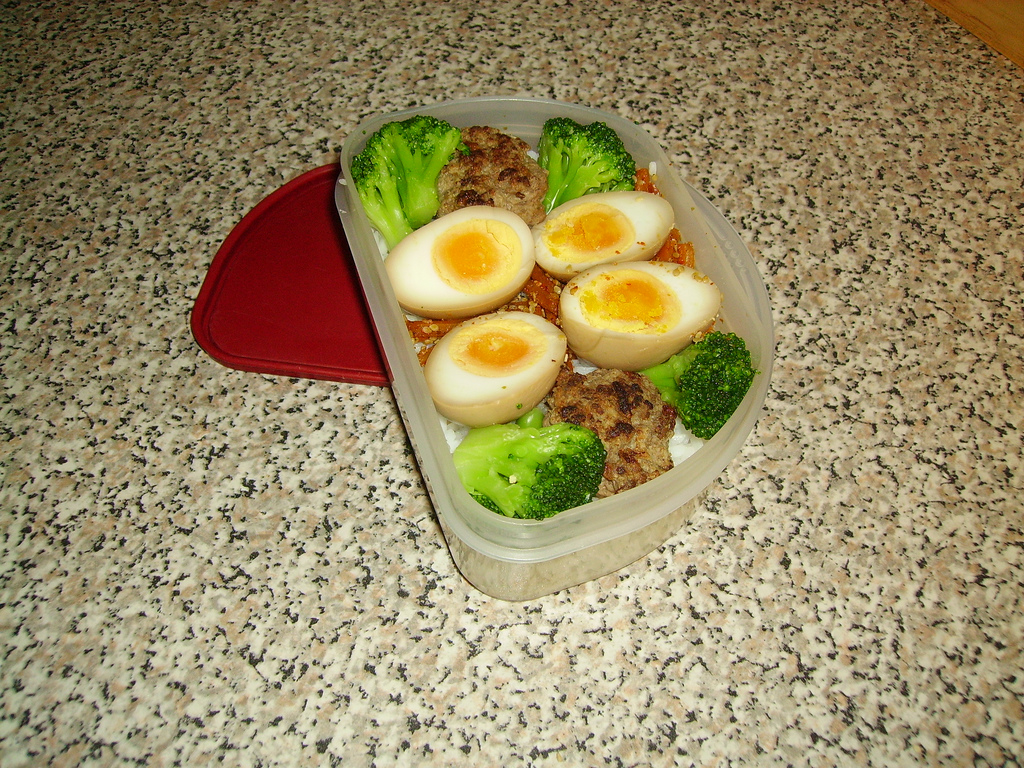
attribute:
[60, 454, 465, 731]
countertop — granite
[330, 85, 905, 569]
container — plastic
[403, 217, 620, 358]
egg — white, golden, hard-boiled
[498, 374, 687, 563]
veggies — green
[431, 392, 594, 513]
vegetable — bright green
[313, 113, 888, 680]
container — plastic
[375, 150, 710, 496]
food — assorted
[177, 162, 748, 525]
container — plastic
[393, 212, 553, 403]
potato — sliced in half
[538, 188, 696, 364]
potato — sliced in half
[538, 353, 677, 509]
steak — sitting in the middle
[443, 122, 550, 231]
steak — sitting in the middle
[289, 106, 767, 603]
container — plastic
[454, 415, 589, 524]
broccoli — green, cooked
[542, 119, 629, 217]
broccoli — cooked, green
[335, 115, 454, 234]
broccoli — green, cooked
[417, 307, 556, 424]
egg — cut in half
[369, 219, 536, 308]
egg — cut in half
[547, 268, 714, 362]
egg — cut in half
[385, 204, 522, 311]
egg — cut in half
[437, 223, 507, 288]
yolk — yellow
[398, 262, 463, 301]
yolk — white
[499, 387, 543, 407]
shell — brown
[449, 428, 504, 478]
stem — green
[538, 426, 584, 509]
bush — green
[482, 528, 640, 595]
tupperware bowl — clear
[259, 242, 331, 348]
lid — red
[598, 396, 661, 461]
meat — brown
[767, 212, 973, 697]
counter — speckled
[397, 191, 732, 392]
eggs — sliced , middle, container